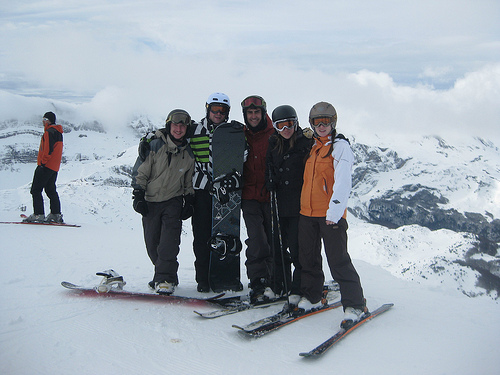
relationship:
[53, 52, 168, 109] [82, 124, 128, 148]
clouds in sky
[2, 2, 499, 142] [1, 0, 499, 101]
clouds in sky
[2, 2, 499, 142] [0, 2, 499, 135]
clouds in sky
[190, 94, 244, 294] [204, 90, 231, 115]
man wearing helmet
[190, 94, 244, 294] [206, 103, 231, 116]
man wearing goggles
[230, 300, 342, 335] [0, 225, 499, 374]
ski on ground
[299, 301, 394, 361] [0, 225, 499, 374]
ski on ground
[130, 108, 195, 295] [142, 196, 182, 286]
man wearing pants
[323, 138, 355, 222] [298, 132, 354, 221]
arm on jacket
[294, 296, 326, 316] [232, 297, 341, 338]
boot on ski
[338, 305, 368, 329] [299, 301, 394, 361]
boot on ski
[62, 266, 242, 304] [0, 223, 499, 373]
snowboard on snow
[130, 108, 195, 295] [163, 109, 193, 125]
man wearing goggles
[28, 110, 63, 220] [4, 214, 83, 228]
man on skis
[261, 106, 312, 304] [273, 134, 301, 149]
girl has hair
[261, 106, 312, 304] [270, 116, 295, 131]
girl wearing goggles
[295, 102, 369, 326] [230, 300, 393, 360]
person on skis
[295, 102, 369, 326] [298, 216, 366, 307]
person wearing pants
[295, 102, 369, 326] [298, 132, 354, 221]
person wearing jacket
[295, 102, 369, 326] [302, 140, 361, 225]
person with jacket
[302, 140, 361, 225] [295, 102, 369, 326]
jacket on person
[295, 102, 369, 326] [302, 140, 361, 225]
person wearing jacket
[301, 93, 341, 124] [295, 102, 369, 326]
helmet on person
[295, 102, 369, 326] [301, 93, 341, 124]
person with helmet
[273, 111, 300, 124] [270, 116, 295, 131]
hair with goggles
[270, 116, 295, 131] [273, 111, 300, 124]
goggles in hair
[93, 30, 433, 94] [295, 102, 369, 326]
area behind person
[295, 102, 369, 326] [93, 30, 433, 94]
person in front of area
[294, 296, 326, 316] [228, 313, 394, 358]
boot on skis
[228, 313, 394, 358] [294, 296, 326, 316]
skis with boot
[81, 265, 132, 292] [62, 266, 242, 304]
boot mount with snowboard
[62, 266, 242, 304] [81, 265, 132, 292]
snowboard with boot mount